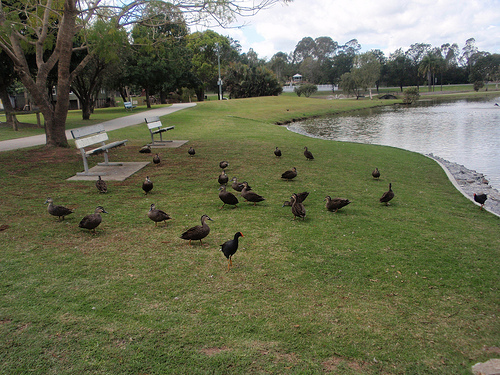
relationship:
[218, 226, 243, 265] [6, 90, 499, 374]
duck standing in grass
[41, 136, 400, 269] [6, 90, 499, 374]
ducks standing on grass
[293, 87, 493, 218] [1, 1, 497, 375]
water at park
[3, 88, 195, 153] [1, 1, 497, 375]
walking path at park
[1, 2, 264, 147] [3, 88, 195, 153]
tree next to walking path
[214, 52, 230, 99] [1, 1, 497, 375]
light pole in park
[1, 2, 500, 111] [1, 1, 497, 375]
trees in park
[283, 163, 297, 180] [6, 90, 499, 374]
duck on grass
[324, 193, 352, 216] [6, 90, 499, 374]
duck on grass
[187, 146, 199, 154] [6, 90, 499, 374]
duck on grass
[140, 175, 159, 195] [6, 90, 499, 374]
duck on grass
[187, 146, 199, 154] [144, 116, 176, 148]
duck near bench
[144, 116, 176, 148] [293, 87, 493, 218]
bench facing in water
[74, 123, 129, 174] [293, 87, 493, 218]
bench facing in water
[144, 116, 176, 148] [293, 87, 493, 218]
bench facing water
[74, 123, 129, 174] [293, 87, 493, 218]
bench facing water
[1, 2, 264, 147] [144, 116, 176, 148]
tree behind bench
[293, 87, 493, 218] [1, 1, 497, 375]
water in park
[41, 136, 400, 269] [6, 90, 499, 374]
ducks on grass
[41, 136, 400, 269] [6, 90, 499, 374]
ducks walking on grass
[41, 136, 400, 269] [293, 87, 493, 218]
ducks walking by water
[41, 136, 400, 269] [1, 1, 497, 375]
ducks walking in park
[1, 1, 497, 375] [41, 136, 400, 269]
park with ducks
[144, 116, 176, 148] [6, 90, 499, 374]
bench on grass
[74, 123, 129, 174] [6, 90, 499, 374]
bench on grass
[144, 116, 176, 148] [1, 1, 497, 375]
bench in park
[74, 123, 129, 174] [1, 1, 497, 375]
bench in park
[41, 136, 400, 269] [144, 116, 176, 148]
ducks walking by bench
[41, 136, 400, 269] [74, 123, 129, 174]
ducks walking by bench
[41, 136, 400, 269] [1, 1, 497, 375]
ducks walking at park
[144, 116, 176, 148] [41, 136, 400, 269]
bench by ducks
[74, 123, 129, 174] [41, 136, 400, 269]
bench by ducks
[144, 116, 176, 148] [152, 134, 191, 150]
bench on slab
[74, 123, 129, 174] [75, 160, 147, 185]
bench on slab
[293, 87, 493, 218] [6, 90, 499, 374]
water and grass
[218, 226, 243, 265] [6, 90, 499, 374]
duck on grass